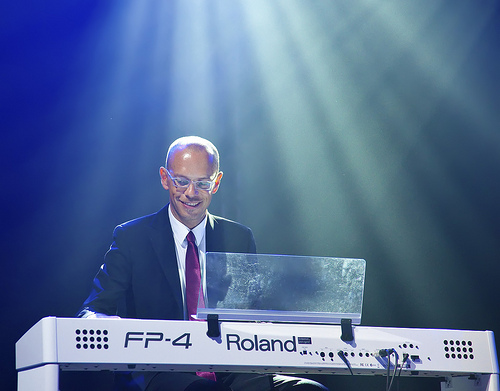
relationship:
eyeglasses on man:
[166, 168, 218, 191] [88, 131, 270, 311]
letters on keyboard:
[123, 331, 192, 350] [12, 313, 492, 370]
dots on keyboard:
[442, 335, 478, 360] [20, 314, 491, 388]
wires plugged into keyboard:
[369, 346, 409, 379] [12, 313, 492, 370]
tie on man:
[183, 229, 211, 324] [77, 134, 325, 390]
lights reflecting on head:
[85, 0, 494, 325] [151, 136, 227, 220]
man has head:
[77, 131, 287, 342] [151, 136, 227, 220]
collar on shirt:
[169, 209, 214, 247] [85, 200, 255, 323]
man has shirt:
[77, 134, 325, 390] [85, 200, 255, 323]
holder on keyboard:
[192, 247, 369, 328] [20, 314, 491, 388]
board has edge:
[7, 313, 493, 373] [210, 321, 360, 336]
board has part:
[192, 249, 367, 329] [303, 251, 318, 278]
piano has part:
[2, 309, 488, 389] [387, 338, 409, 360]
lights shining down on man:
[85, 0, 494, 325] [77, 134, 325, 390]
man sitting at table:
[77, 134, 325, 390] [10, 311, 499, 390]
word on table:
[226, 333, 297, 352] [10, 311, 499, 390]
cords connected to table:
[338, 348, 418, 377] [10, 311, 499, 390]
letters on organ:
[120, 319, 191, 360] [9, 313, 491, 388]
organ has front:
[9, 313, 491, 388] [60, 327, 487, 357]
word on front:
[227, 330, 300, 359] [60, 327, 487, 357]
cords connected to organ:
[338, 348, 410, 377] [7, 311, 493, 377]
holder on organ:
[192, 247, 369, 328] [7, 311, 493, 377]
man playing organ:
[77, 134, 325, 390] [9, 313, 491, 388]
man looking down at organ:
[77, 134, 325, 390] [7, 300, 492, 381]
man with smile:
[77, 134, 325, 390] [172, 195, 205, 210]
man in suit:
[77, 134, 325, 390] [86, 210, 326, 388]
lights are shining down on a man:
[85, 5, 496, 326] [77, 134, 325, 390]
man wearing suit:
[77, 134, 325, 390] [83, 204, 283, 321]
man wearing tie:
[77, 134, 325, 390] [178, 233, 206, 317]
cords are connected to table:
[155, 367, 241, 387] [10, 311, 499, 390]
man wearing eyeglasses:
[77, 134, 325, 390] [160, 161, 227, 192]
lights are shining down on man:
[85, 5, 496, 326] [77, 134, 325, 390]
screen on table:
[189, 244, 372, 337] [10, 311, 499, 390]